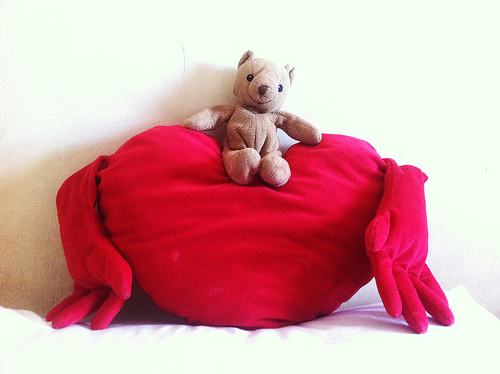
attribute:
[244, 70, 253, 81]
eye — black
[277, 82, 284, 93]
eye — black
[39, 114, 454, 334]
heart — stuffed, red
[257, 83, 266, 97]
nose — brown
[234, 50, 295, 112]
head — brown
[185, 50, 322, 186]
bear — small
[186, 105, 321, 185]
body — brown